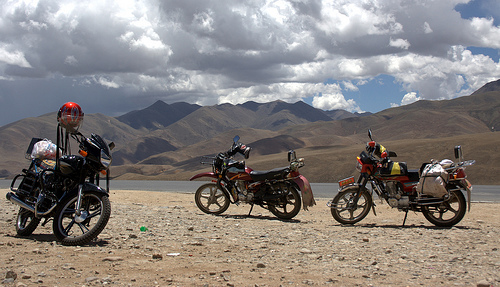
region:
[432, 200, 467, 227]
back wheel on right bike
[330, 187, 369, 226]
front wheel on right bike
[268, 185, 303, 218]
back wheel on middle bike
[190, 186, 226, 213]
front wheel on middle bike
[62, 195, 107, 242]
front wheel on left bike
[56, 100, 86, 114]
red helmet on bike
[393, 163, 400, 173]
yellow paint on bike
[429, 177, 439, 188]
white bag on bike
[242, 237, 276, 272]
rocks in dirt on ground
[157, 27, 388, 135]
Clouds over a mountain top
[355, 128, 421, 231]
A motorcycle leaning on a kickstand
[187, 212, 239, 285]
A gravel and dirt road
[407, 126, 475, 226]
A white bag strapped to the back of a motorcycle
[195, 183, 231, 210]
Spokes inside a tire wheel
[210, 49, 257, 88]
Dark gray cloudy sky.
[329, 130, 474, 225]
Motor bike with white bag strapped across.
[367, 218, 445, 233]
Shadow cast from motor bike.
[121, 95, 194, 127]
Darkness cast on mountain from clouds.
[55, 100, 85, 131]
Shiny red helmet on bike.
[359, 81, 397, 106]
Clear blue open space.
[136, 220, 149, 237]
Green bottle among gravel.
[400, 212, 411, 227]
Kickstand holding up bike.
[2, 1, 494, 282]
three motorcycles in a remote area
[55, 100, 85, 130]
red helmet set on the handlebars of a motorcycle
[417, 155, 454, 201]
white storage packs on the back of a motorcycle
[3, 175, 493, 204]
river in a rural mountainous area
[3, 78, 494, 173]
mountains with sunshine and shady areas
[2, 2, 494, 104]
mostly cloudy sky with patches of blue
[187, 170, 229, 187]
red front fender on a motorcycle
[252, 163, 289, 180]
black vinyl seat on a motorcycle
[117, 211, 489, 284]
rocky area on sand near a river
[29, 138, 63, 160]
plastic bag used to protect gear from getting wet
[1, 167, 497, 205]
we're at the edge of a lake or big river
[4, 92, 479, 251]
three motorcycles parked in the wilderness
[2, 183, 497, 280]
motorcycles on a rocky dirt shore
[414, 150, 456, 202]
this motorcycle has packs attached to the back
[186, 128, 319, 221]
this motorcycle has black and red detailing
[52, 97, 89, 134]
helmet hung on this motorcycle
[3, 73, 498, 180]
mountains on the other side of the water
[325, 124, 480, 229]
red and yellow accents on this motorcycle